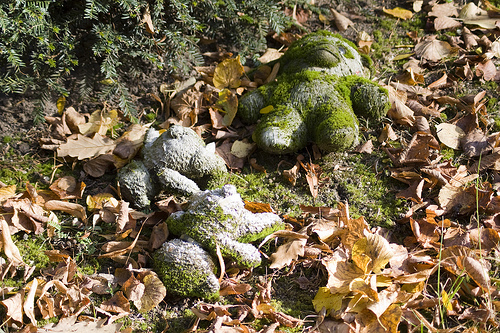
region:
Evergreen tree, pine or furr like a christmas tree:
[38, 17, 196, 98]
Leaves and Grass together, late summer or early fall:
[316, 219, 493, 331]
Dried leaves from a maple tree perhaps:
[34, 111, 119, 186]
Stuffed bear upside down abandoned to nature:
[99, 112, 235, 218]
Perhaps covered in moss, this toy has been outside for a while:
[231, 24, 416, 157]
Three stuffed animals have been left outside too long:
[93, 24, 426, 305]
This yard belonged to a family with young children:
[66, 27, 427, 296]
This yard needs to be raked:
[294, 176, 491, 320]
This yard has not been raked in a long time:
[100, 26, 440, 278]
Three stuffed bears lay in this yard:
[102, 24, 422, 299]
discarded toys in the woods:
[118, 32, 393, 298]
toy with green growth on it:
[243, 32, 390, 152]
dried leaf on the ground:
[53, 132, 120, 162]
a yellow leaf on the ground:
[349, 235, 372, 275]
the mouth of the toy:
[309, 48, 339, 63]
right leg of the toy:
[254, 108, 311, 153]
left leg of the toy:
[312, 109, 361, 151]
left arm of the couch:
[351, 72, 389, 124]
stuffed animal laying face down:
[119, 122, 226, 207]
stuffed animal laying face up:
[239, 29, 395, 157]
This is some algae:
[226, 25, 431, 166]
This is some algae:
[164, 232, 217, 310]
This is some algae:
[198, 213, 265, 298]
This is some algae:
[232, 197, 286, 252]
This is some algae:
[146, 112, 245, 189]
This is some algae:
[111, 142, 168, 229]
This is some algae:
[247, 81, 302, 156]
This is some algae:
[266, 139, 415, 235]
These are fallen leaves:
[396, 100, 495, 235]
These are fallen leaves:
[286, 214, 461, 322]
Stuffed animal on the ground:
[232, 28, 404, 149]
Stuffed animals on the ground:
[117, 29, 397, 299]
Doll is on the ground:
[232, 27, 391, 154]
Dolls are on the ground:
[109, 30, 394, 300]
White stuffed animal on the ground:
[112, 121, 232, 210]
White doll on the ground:
[111, 120, 231, 211]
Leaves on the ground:
[0, 0, 496, 330]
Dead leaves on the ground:
[0, 0, 496, 330]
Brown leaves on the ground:
[0, 0, 497, 331]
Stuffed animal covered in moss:
[237, 27, 392, 154]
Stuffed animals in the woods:
[74, 16, 414, 313]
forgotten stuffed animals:
[92, 23, 419, 309]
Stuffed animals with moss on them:
[101, 13, 438, 303]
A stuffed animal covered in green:
[243, 20, 400, 167]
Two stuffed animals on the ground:
[104, 117, 291, 314]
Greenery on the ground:
[18, 7, 264, 97]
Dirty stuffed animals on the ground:
[77, 28, 401, 293]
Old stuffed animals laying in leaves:
[111, 18, 388, 295]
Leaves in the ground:
[399, 28, 492, 326]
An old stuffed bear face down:
[128, 161, 284, 307]